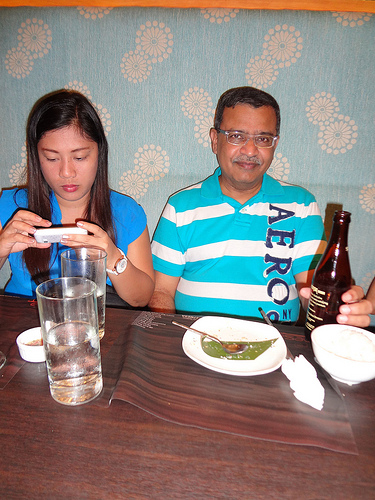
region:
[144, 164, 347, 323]
Man wearing a shirt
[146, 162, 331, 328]
Man is wearing a shirt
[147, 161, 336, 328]
Man wearing a blue and white shirt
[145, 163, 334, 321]
Man is wearing a blue and white shirt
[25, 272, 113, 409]
Glass on a table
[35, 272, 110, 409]
Glass is on a table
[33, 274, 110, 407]
Water glass on a table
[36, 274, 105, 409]
Water glass is on a table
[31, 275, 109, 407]
Glass of water on a table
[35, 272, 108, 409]
Glass of water is on a table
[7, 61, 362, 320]
man and woman at a table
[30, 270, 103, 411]
glass with liquid in it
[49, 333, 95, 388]
liquid in the glass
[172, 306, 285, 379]
plate on the table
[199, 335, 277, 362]
food on the plate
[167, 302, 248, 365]
utensil on the plate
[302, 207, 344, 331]
bottled beverage in man's hand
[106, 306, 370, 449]
mat under the plate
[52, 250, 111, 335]
glass with liquid in it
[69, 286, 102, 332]
liquid in the glass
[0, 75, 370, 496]
man and woman at the table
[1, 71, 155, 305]
woman checking her phone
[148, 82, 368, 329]
man holding a beer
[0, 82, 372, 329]
man and woman both wearing blue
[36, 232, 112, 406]
two clear glasses with water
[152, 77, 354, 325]
man with blue and white shirt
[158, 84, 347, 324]
man wearing a striped shirt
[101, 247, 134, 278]
white watch on the woman's wrist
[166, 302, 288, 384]
white plate with a spoon on top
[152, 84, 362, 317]
MAN SEATED FOR DINNER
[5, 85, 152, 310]
WOMAN SEATED FOR DINNER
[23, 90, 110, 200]
HEAD OF SEATED WOMAN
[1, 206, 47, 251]
HAND OF SEATED WOMAN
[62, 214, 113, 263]
HAND OF SEATED WOMAN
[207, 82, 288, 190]
HEAD OF SEATED MAN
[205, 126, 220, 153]
EAR OF SEATED MAN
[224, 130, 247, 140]
EYE OF SEATED MAN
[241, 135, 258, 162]
NOSE OF SEATED MAN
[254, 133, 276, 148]
EYE OF SEATED MAN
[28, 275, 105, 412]
Large glass bottle of water sitting on a table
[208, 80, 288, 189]
Man with short black hair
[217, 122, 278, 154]
See through plastic glasses with blue pieces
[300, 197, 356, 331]
Tinted glass bottle mostly empty on a table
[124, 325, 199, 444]
Table cloth painted almost the same color as the table below it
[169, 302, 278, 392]
White plate with a gray metal spoon on it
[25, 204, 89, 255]
White cell phone being held by a girl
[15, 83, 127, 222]
Girl with long straight brown colored hair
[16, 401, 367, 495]
Dark colored wooden table with visible grain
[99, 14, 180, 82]
Blue wall paper with white designs on it